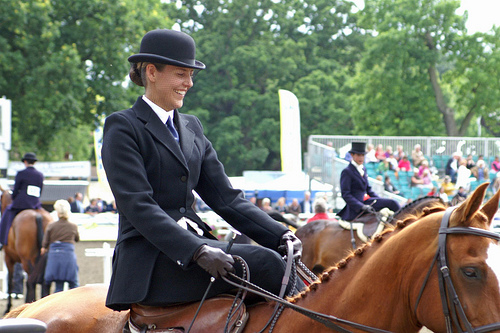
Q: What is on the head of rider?
A: Hat.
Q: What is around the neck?
A: Tie.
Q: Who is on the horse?
A: A lady.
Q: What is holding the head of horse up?
A: Neck.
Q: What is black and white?
A: Suit.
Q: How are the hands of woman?
A: Covered.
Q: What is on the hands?
A: Gloves.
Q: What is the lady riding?
A: Horse.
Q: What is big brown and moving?
A: Horse.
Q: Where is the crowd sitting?
A: Bleachers.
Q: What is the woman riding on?
A: A horse.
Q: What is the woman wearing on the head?
A: A hat.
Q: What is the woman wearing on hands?
A: Gloves.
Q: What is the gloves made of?
A: Leather.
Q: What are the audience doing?
A: Watching.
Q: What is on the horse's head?
A: Halter.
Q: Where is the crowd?
A: In the background in the stands.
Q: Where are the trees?
A: In the background behind the audience.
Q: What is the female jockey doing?
A: Riding the horse.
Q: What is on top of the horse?
A: A female jockey.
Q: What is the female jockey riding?
A: Horse.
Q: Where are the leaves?
A: In the trees in the background.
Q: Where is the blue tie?
A: On the female jockey.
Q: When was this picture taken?
A: Daytime.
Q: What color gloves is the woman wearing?
A: Black.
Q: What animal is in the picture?
A: Horse.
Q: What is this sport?
A: Equestrian.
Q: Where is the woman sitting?
A: On horse.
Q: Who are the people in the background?
A: Spectators.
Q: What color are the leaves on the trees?
A: Green.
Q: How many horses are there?
A: 3.